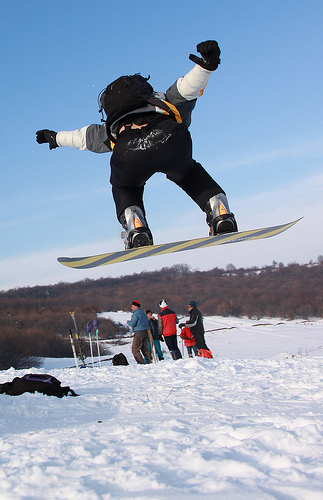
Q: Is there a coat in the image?
A: Yes, there is a coat.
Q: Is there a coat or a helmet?
A: Yes, there is a coat.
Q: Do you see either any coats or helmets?
A: Yes, there is a coat.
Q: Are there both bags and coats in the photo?
A: Yes, there are both a coat and a bag.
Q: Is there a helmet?
A: No, there are no helmets.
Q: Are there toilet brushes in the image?
A: No, there are no toilet brushes.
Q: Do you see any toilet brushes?
A: No, there are no toilet brushes.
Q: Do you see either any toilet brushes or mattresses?
A: No, there are no toilet brushes or mattresses.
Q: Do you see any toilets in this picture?
A: No, there are no toilets.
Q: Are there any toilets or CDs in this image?
A: No, there are no toilets or cds.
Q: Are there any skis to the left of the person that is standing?
A: Yes, there is a ski to the left of the person.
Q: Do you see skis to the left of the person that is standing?
A: Yes, there is a ski to the left of the person.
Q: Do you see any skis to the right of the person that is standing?
A: No, the ski is to the left of the person.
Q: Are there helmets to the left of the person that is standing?
A: No, there is a ski to the left of the person.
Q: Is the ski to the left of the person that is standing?
A: Yes, the ski is to the left of the person.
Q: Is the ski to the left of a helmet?
A: No, the ski is to the left of the person.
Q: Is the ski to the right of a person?
A: No, the ski is to the left of a person.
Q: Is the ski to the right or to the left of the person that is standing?
A: The ski is to the left of the person.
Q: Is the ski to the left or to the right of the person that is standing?
A: The ski is to the left of the person.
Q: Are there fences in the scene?
A: No, there are no fences.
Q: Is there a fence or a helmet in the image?
A: No, there are no fences or helmets.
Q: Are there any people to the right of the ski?
A: Yes, there is a person to the right of the ski.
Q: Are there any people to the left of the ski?
A: No, the person is to the right of the ski.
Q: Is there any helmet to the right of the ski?
A: No, there is a person to the right of the ski.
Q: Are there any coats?
A: Yes, there is a coat.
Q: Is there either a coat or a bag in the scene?
A: Yes, there is a coat.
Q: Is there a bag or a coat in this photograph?
A: Yes, there is a coat.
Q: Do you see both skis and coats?
A: Yes, there are both a coat and skis.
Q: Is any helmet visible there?
A: No, there are no helmets.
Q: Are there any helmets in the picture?
A: No, there are no helmets.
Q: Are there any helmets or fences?
A: No, there are no helmets or fences.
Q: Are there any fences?
A: No, there are no fences.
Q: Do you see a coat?
A: Yes, there is a coat.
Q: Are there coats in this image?
A: Yes, there is a coat.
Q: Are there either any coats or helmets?
A: Yes, there is a coat.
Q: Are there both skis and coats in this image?
A: Yes, there are both a coat and skis.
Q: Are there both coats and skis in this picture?
A: Yes, there are both a coat and skis.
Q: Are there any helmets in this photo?
A: No, there are no helmets.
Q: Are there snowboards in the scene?
A: Yes, there is a snowboard.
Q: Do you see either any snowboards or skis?
A: Yes, there is a snowboard.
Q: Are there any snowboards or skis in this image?
A: Yes, there is a snowboard.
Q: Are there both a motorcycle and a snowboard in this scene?
A: No, there is a snowboard but no motorcycles.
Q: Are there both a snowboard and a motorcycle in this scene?
A: No, there is a snowboard but no motorcycles.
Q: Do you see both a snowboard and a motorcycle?
A: No, there is a snowboard but no motorcycles.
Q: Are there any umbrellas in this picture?
A: No, there are no umbrellas.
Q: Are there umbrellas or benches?
A: No, there are no umbrellas or benches.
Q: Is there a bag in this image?
A: Yes, there is a bag.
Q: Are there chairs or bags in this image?
A: Yes, there is a bag.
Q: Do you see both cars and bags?
A: No, there is a bag but no cars.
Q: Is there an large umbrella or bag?
A: Yes, there is a large bag.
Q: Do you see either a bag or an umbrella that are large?
A: Yes, the bag is large.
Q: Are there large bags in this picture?
A: Yes, there is a large bag.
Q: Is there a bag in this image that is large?
A: Yes, there is a bag that is large.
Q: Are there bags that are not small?
A: Yes, there is a large bag.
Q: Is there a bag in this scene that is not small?
A: Yes, there is a large bag.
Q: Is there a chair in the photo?
A: No, there are no chairs.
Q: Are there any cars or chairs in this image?
A: No, there are no chairs or cars.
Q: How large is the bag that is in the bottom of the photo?
A: The bag is large.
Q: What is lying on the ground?
A: The bag is lying on the ground.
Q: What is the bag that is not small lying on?
A: The bag is lying on the ground.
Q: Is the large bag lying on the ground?
A: Yes, the bag is lying on the ground.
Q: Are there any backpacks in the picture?
A: Yes, there is a backpack.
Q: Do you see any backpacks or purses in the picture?
A: Yes, there is a backpack.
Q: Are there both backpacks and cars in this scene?
A: No, there is a backpack but no cars.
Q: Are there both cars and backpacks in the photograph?
A: No, there is a backpack but no cars.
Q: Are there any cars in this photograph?
A: No, there are no cars.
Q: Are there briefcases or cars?
A: No, there are no cars or briefcases.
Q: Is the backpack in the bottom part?
A: No, the backpack is in the top of the image.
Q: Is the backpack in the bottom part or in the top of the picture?
A: The backpack is in the top of the image.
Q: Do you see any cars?
A: No, there are no cars.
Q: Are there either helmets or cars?
A: No, there are no cars or helmets.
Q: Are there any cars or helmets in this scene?
A: No, there are no cars or helmets.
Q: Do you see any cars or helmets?
A: No, there are no cars or helmets.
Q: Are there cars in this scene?
A: No, there are no cars.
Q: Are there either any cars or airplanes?
A: No, there are no cars or airplanes.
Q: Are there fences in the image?
A: No, there are no fences.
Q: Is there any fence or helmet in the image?
A: No, there are no fences or helmets.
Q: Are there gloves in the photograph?
A: Yes, there are gloves.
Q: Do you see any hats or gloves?
A: Yes, there are gloves.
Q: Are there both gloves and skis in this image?
A: Yes, there are both gloves and skis.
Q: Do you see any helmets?
A: No, there are no helmets.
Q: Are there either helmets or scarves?
A: No, there are no helmets or scarves.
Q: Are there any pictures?
A: No, there are no pictures.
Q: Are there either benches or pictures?
A: No, there are no pictures or benches.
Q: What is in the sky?
A: The clouds are in the sky.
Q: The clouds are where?
A: The clouds are in the sky.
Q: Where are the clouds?
A: The clouds are in the sky.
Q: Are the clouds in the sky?
A: Yes, the clouds are in the sky.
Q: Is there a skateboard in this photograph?
A: No, there are no skateboards.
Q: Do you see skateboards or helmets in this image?
A: No, there are no skateboards or helmets.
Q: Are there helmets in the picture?
A: No, there are no helmets.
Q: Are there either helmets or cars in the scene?
A: No, there are no helmets or cars.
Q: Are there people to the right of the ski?
A: Yes, there is a person to the right of the ski.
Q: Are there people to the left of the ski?
A: No, the person is to the right of the ski.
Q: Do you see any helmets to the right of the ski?
A: No, there is a person to the right of the ski.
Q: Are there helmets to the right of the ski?
A: No, there is a person to the right of the ski.